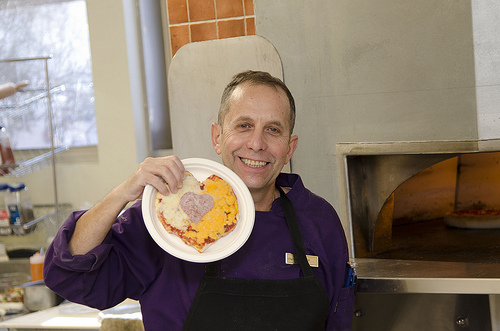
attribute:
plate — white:
[123, 156, 250, 289]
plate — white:
[90, 171, 281, 232]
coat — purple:
[71, 210, 329, 247]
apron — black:
[176, 264, 344, 303]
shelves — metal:
[7, 49, 59, 259]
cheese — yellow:
[199, 171, 239, 234]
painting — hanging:
[352, 141, 495, 261]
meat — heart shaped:
[192, 185, 229, 224]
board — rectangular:
[154, 28, 301, 167]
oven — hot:
[360, 229, 487, 329]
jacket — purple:
[119, 163, 443, 303]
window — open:
[11, 51, 118, 171]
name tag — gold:
[278, 223, 374, 315]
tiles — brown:
[172, 24, 277, 48]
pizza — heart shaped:
[116, 137, 363, 329]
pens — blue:
[338, 257, 383, 297]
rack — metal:
[35, 42, 57, 216]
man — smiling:
[180, 57, 354, 217]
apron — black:
[176, 253, 333, 319]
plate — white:
[82, 136, 313, 259]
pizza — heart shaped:
[140, 160, 298, 282]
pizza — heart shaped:
[160, 187, 268, 253]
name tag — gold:
[286, 238, 322, 265]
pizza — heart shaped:
[111, 120, 308, 268]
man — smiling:
[173, 87, 348, 187]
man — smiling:
[223, 104, 343, 245]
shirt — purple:
[80, 207, 476, 271]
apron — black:
[166, 178, 366, 326]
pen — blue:
[340, 253, 381, 304]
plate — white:
[122, 148, 245, 254]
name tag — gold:
[275, 220, 321, 261]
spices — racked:
[3, 87, 73, 278]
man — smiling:
[202, 33, 337, 184]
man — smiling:
[198, 69, 369, 238]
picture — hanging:
[370, 122, 498, 262]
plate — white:
[170, 154, 247, 274]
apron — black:
[195, 273, 355, 320]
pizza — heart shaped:
[72, 171, 274, 245]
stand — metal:
[10, 79, 74, 254]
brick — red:
[141, 0, 261, 68]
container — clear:
[0, 180, 50, 264]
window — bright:
[9, 29, 116, 167]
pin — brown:
[0, 71, 61, 86]